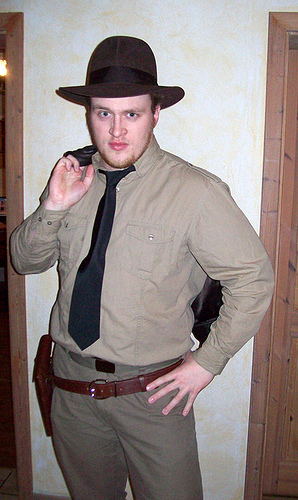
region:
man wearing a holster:
[16, 327, 205, 436]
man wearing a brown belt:
[40, 365, 177, 406]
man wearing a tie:
[53, 145, 170, 365]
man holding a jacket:
[60, 129, 103, 174]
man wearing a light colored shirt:
[16, 109, 269, 396]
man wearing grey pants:
[46, 343, 206, 498]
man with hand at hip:
[147, 279, 225, 424]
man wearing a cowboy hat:
[46, 8, 194, 125]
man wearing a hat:
[49, 19, 202, 118]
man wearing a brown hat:
[62, 33, 198, 119]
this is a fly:
[83, 390, 124, 438]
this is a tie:
[58, 160, 151, 357]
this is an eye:
[92, 106, 121, 121]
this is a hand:
[36, 150, 108, 204]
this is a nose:
[103, 108, 131, 139]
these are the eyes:
[82, 101, 149, 133]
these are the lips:
[98, 135, 132, 151]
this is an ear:
[147, 96, 164, 130]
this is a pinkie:
[179, 378, 202, 426]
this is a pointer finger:
[137, 365, 184, 390]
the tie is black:
[62, 157, 129, 351]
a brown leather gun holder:
[14, 326, 76, 446]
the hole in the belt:
[118, 387, 121, 390]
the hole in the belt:
[108, 388, 111, 392]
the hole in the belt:
[100, 388, 103, 392]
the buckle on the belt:
[88, 378, 109, 399]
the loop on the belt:
[137, 373, 145, 390]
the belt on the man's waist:
[48, 358, 183, 398]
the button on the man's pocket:
[148, 233, 153, 239]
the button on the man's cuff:
[46, 220, 51, 225]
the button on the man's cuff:
[37, 216, 42, 221]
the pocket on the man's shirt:
[120, 223, 175, 280]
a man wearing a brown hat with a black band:
[53, 30, 184, 112]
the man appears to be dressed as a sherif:
[7, 34, 279, 496]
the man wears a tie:
[67, 164, 135, 352]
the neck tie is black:
[65, 165, 137, 352]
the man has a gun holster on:
[25, 340, 65, 435]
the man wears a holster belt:
[47, 363, 182, 403]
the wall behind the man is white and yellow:
[32, 12, 244, 491]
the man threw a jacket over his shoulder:
[43, 144, 241, 353]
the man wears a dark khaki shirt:
[13, 146, 267, 365]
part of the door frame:
[1, 9, 33, 493]